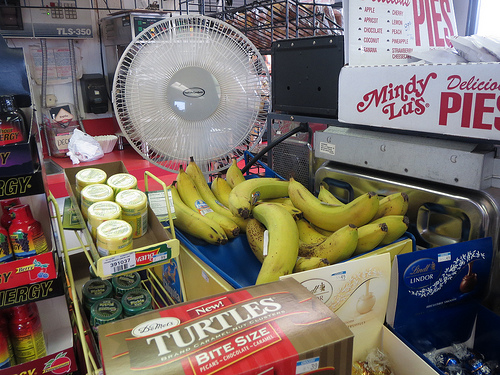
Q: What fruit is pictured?
A: Bananas.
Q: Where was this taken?
A: A market.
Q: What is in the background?
A: A white fan.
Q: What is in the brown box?
A: Bite size Turtles.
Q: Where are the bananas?
A: On top of a box.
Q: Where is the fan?
A: Behind the bananas.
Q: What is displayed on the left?
A: Energy drinks.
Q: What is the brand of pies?
A: Mindy Lu's.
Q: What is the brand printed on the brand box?
A: Turtles.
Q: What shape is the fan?
A: Round shape.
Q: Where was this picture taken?
A: A convenience store.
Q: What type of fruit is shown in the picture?
A: Bananas.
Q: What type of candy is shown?
A: Turtles.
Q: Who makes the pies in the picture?
A: Mindy Lu's.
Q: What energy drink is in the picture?
A: 5 hour energy.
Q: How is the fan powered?
A: Electricity.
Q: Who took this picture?
A: An employee.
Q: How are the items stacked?
A: On the shelf.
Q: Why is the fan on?
A: To cool the store.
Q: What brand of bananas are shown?
A: Chiquita.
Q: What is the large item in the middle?
A: A fan.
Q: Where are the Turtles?
A: In front.